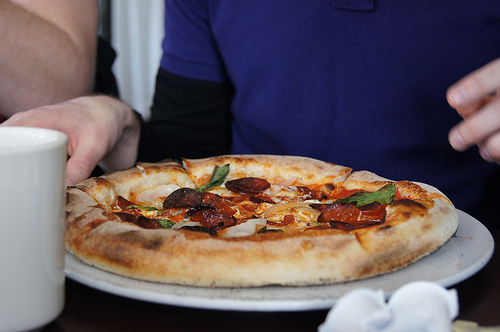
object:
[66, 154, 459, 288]
pizza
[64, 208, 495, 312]
plate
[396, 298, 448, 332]
white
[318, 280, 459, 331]
napkin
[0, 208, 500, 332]
table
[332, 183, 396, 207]
leaf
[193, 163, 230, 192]
basil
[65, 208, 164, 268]
burned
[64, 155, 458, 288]
crust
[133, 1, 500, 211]
shirt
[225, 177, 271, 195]
pepperoni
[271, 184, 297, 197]
cheese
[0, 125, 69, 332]
cup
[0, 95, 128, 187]
hand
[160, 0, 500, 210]
blue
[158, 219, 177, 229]
spinach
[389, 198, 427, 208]
done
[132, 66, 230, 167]
black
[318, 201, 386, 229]
red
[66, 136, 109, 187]
finger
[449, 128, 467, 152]
nail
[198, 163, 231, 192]
green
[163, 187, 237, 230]
toppings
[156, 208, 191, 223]
sauce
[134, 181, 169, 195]
dough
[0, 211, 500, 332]
brown